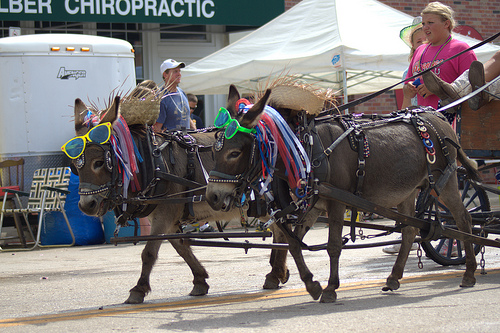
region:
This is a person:
[145, 55, 225, 212]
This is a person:
[405, 1, 482, 173]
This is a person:
[143, 42, 207, 196]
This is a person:
[416, 0, 488, 161]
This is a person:
[143, 42, 190, 177]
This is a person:
[183, 82, 208, 170]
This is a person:
[152, 39, 189, 164]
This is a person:
[416, 0, 491, 177]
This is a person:
[390, 0, 430, 110]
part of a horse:
[276, 187, 279, 208]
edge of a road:
[342, 317, 344, 322]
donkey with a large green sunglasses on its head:
[201, 80, 486, 307]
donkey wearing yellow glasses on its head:
[56, 91, 297, 303]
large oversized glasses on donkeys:
[56, 78, 484, 308]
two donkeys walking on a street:
[56, 88, 480, 305]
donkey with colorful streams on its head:
[203, 82, 481, 309]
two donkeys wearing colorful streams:
[56, 82, 481, 307]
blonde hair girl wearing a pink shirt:
[399, 0, 476, 110]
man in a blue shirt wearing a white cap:
[154, 57, 193, 133]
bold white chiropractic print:
[61, 0, 221, 17]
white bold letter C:
[201, 0, 216, 17]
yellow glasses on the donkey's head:
[57, 115, 115, 158]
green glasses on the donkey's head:
[207, 106, 251, 145]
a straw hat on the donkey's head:
[94, 89, 166, 126]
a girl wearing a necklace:
[415, 6, 472, 118]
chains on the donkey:
[101, 125, 167, 218]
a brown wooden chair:
[2, 156, 28, 241]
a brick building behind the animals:
[290, 0, 498, 125]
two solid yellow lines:
[2, 263, 497, 328]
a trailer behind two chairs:
[0, 26, 132, 198]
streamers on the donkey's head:
[219, 96, 309, 202]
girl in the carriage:
[382, 3, 472, 71]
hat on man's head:
[135, 45, 206, 87]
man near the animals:
[155, 37, 211, 107]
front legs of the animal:
[110, 222, 227, 297]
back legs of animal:
[342, 190, 482, 305]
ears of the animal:
[200, 80, 280, 127]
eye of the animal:
[209, 132, 258, 174]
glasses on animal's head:
[27, 114, 120, 176]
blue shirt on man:
[150, 81, 198, 133]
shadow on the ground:
[218, 289, 264, 332]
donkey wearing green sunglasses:
[203, 77, 483, 306]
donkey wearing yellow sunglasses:
[54, 94, 296, 304]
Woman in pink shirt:
[407, 0, 481, 110]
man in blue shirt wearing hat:
[147, 55, 194, 135]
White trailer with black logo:
[1, 34, 146, 159]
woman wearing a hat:
[399, 12, 427, 59]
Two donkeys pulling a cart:
[69, 40, 499, 306]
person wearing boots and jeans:
[421, 47, 498, 112]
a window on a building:
[36, 20, 81, 35]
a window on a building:
[100, 19, 146, 87]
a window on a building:
[163, 22, 206, 39]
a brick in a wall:
[362, 101, 372, 106]